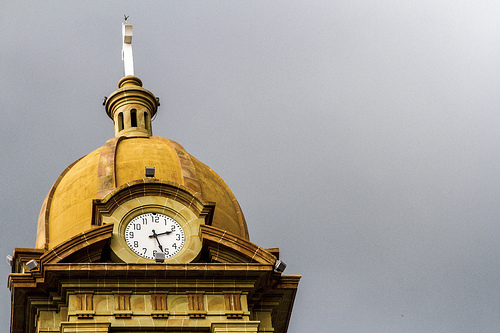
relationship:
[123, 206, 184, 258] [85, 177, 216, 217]
clock under an arch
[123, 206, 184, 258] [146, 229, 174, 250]
clock has black arrows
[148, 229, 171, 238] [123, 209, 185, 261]
hour hand on clock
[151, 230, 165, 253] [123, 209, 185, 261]
minute hand on clock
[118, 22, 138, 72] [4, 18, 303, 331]
cross on tower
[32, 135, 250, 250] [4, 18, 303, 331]
dome on tower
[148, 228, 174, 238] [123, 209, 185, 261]
hour hand on clock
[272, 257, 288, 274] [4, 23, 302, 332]
light on building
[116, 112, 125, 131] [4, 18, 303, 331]
window on tower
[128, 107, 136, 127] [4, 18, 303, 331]
window on tower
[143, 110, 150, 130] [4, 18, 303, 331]
window on tower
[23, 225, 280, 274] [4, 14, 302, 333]
arch on building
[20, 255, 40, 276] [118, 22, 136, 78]
light illuminates cross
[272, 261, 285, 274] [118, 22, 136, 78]
light illuminates cross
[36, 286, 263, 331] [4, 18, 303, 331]
stonework on tower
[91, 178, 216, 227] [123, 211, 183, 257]
arch above clock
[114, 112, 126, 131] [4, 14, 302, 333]
window on building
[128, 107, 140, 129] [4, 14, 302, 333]
window on building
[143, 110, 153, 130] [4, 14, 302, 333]
window on building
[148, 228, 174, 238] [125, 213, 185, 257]
hour hand on clock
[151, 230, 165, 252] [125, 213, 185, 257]
minute hand on clock